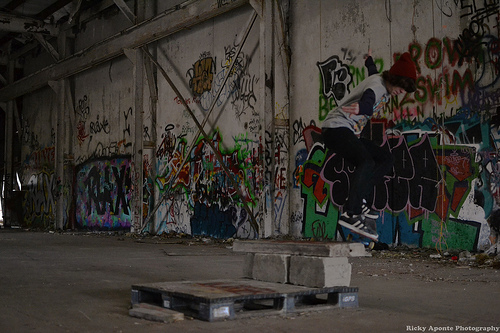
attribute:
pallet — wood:
[129, 273, 359, 312]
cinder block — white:
[246, 254, 354, 290]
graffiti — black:
[293, 12, 498, 266]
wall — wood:
[6, 11, 499, 264]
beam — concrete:
[128, 44, 148, 236]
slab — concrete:
[229, 239, 370, 260]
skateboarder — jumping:
[319, 42, 417, 241]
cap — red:
[392, 53, 422, 80]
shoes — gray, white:
[340, 204, 384, 243]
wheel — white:
[368, 241, 376, 252]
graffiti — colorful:
[75, 155, 134, 229]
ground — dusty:
[2, 230, 499, 333]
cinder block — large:
[290, 259, 351, 287]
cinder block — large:
[248, 254, 288, 285]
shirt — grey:
[322, 73, 388, 126]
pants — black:
[321, 123, 377, 217]